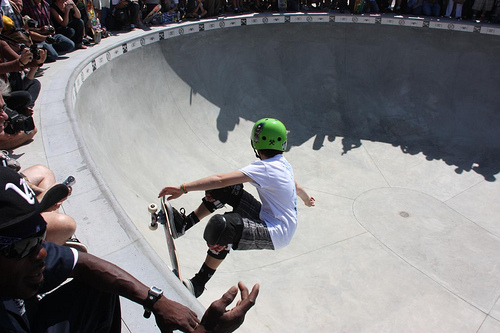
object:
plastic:
[250, 117, 287, 151]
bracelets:
[180, 183, 188, 194]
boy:
[158, 118, 315, 298]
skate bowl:
[64, 15, 499, 333]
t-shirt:
[238, 154, 297, 250]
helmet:
[250, 117, 287, 157]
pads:
[203, 214, 226, 246]